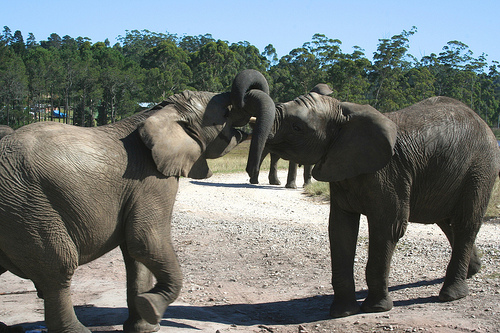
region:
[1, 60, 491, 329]
two elephants with trunks coiled together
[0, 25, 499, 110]
a line of green trees in the background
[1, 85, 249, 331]
elephant lifting its front leg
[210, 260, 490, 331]
elephant shadow on the ground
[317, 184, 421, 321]
elephant's two front legs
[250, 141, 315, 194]
four elephant legs in the background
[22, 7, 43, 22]
white clouds in blue sky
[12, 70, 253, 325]
large gray elephant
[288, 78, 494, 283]
large gray elephant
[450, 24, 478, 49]
white clouds in blue sky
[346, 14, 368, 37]
white clouds in blue sky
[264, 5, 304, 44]
white clouds in blue sky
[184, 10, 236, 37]
white clouds in blue sky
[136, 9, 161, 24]
white clouds in blue sky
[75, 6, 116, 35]
white clouds in blue sky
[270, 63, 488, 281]
elephant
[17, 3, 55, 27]
white clouds in blue sky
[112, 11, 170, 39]
white clouds in blue sky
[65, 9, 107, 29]
white clouds in blue sky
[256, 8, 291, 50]
white clouds in blue sky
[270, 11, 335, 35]
white clouds in blue sky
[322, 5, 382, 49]
white clouds in blue sky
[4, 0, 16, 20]
white clouds in blue sky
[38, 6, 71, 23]
white clouds in blue sky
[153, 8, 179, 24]
white clouds in blue sky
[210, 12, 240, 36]
white clouds in blue sky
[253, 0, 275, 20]
white clouds in blue sky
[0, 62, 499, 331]
two elephant standing on dirt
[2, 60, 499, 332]
two elephants playing with trunks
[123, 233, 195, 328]
one raised elephant leg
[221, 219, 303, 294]
rocks on dirt ground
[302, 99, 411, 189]
one elephant ear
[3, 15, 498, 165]
line of tall trees bordering dirt ground ground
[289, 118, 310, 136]
one elephant eye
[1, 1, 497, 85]
blue sky above trees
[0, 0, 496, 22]
clear blue cloudless sky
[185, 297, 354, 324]
shadow of elephant cast upon loose dirt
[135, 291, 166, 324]
lifted elephant foot in sunlight